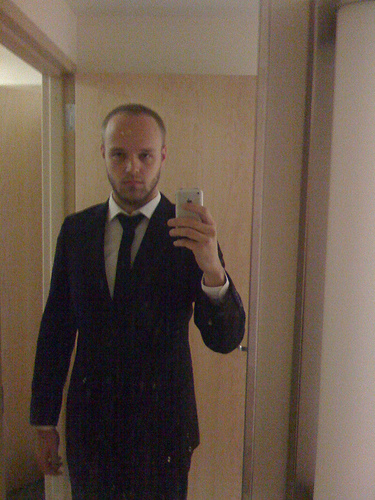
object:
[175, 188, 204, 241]
cellphone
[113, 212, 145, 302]
tie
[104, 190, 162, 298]
shirt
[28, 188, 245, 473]
coat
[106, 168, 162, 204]
beard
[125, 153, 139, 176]
nose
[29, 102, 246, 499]
man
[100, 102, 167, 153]
hair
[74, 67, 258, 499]
door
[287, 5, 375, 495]
wall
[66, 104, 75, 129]
hinge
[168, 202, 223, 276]
hand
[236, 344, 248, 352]
handle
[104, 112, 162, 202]
face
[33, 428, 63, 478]
hand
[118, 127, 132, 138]
dirt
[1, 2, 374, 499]
mirror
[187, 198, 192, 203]
logo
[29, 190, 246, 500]
suit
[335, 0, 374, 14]
edge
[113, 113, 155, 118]
hairline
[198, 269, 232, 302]
cuffs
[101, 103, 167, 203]
head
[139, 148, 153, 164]
eyes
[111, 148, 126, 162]
eyes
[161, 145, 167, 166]
ear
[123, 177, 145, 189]
lips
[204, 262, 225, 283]
wrist